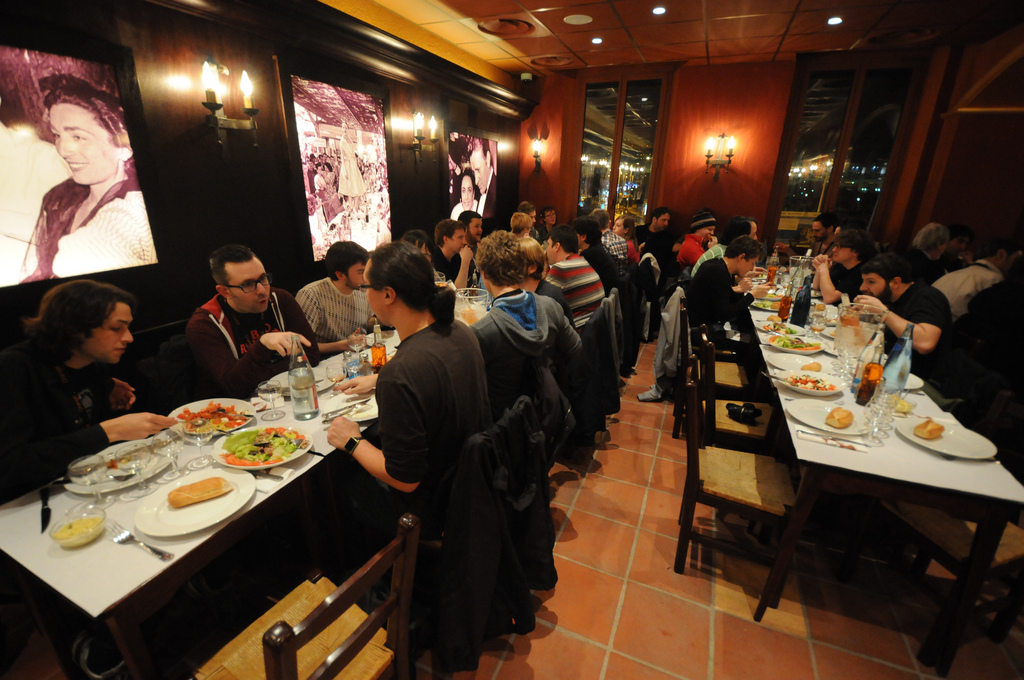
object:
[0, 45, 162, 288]
photo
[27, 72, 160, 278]
woman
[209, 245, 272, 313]
head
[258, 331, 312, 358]
hand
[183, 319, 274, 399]
arm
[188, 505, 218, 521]
white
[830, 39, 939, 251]
windows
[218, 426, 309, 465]
food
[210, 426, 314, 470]
plate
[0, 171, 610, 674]
table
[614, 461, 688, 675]
floor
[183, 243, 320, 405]
man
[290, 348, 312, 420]
glass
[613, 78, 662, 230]
window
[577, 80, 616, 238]
window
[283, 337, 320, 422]
bottle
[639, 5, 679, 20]
recessed lights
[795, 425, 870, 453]
cover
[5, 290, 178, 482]
woman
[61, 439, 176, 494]
plate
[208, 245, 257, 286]
hair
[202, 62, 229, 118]
light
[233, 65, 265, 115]
light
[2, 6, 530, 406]
wall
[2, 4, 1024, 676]
restaurant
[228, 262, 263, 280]
forehead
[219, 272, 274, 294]
glasses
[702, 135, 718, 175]
lights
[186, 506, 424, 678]
chair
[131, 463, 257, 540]
plate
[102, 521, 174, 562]
silverware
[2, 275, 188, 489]
person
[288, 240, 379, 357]
person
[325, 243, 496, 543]
person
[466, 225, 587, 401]
person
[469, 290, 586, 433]
hoodie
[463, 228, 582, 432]
boy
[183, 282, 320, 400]
hoodie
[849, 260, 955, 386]
man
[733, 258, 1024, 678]
table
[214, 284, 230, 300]
ear